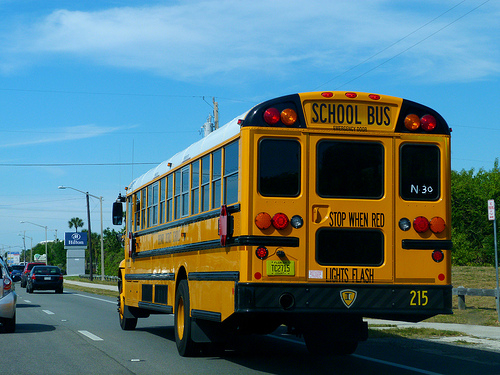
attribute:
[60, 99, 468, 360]
bus — on the road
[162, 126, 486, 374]
bus — on the road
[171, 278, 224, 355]
tire — on the road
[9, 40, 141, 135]
clouds — above bus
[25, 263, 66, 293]
car — next to bus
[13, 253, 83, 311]
traffic — heavy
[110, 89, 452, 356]
automobile — on the road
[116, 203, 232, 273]
signs — on the road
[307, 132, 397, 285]
back door — on bus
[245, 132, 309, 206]
window — on the bus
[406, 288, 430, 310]
number — on the bus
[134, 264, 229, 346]
wheel — on the road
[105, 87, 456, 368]
bus — on the road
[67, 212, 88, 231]
palm tree — on the road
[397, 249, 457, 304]
bus — on the road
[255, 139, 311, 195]
windows — on the bus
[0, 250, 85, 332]
cars — next to bus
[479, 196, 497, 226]
sign — on the road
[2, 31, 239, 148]
sky — blue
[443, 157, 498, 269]
leaves — next to bus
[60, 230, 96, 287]
sign — on bus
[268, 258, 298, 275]
license plate — on the road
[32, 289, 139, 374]
lines — white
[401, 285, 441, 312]
number — on the bus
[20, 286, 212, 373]
street — under bus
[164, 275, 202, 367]
wheel — on the road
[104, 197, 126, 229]
mirror — driver's